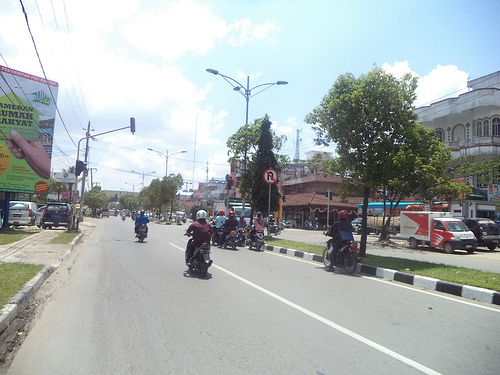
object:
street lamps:
[205, 68, 248, 100]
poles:
[242, 76, 252, 217]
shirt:
[185, 221, 213, 248]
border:
[262, 244, 499, 311]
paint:
[490, 292, 500, 306]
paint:
[434, 280, 466, 297]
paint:
[360, 264, 378, 276]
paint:
[312, 254, 324, 262]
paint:
[279, 247, 288, 254]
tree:
[307, 119, 475, 243]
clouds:
[375, 60, 475, 109]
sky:
[0, 0, 500, 196]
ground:
[263, 236, 500, 293]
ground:
[0, 225, 84, 321]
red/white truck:
[399, 210, 479, 253]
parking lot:
[388, 235, 500, 253]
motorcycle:
[182, 215, 187, 223]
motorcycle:
[122, 213, 127, 222]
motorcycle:
[266, 221, 279, 236]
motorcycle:
[321, 229, 362, 274]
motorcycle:
[134, 223, 149, 244]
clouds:
[268, 117, 338, 160]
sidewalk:
[0, 229, 83, 265]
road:
[0, 215, 500, 375]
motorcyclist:
[325, 210, 356, 272]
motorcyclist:
[135, 210, 150, 239]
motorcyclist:
[217, 210, 239, 248]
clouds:
[51, 128, 231, 194]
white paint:
[460, 284, 500, 305]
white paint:
[355, 263, 368, 272]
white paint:
[375, 266, 399, 280]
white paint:
[287, 249, 299, 256]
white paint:
[303, 252, 318, 260]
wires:
[88, 160, 205, 184]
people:
[246, 212, 267, 247]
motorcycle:
[218, 229, 239, 250]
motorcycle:
[235, 226, 250, 247]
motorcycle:
[246, 228, 267, 251]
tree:
[301, 61, 423, 259]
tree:
[225, 111, 290, 227]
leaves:
[378, 87, 384, 92]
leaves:
[252, 128, 256, 132]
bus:
[354, 200, 447, 237]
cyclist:
[184, 209, 214, 266]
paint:
[412, 274, 441, 290]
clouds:
[0, 0, 290, 130]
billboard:
[0, 65, 59, 195]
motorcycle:
[184, 229, 214, 278]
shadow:
[182, 269, 213, 280]